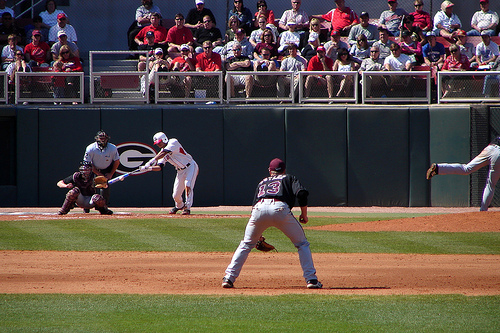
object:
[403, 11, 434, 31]
shirt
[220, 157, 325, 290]
pitcher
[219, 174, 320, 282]
uniform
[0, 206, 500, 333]
field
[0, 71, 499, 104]
fence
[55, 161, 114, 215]
catcher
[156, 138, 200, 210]
uniform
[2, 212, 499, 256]
grass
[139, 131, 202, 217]
player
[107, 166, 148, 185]
bat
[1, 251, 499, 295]
dirt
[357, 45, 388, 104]
spectator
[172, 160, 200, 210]
pants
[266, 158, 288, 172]
cap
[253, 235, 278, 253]
glove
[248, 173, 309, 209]
shirt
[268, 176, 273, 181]
letter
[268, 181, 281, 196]
number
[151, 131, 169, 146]
helmet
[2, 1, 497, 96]
crowd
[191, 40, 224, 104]
person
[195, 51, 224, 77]
red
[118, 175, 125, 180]
ball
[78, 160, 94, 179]
helmet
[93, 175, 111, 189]
mitt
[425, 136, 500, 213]
man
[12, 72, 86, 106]
rail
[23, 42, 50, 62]
shirt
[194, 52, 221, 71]
shirt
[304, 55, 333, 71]
shirt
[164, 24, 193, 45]
shirt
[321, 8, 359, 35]
shirt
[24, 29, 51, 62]
man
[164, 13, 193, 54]
man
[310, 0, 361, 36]
man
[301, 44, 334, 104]
man